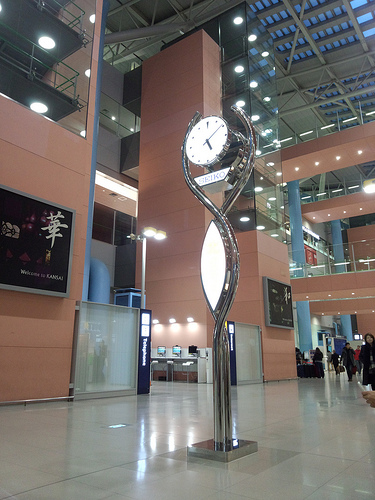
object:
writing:
[39, 203, 68, 256]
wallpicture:
[0, 183, 76, 300]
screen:
[261, 268, 300, 334]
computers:
[158, 343, 169, 358]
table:
[154, 356, 197, 366]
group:
[296, 332, 374, 377]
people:
[309, 343, 327, 380]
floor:
[5, 402, 375, 498]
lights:
[230, 9, 247, 34]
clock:
[180, 116, 232, 167]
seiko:
[195, 169, 225, 181]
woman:
[358, 332, 372, 395]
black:
[355, 343, 374, 387]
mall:
[1, 2, 367, 485]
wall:
[2, 97, 80, 402]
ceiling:
[117, 5, 374, 113]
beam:
[291, 188, 322, 362]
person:
[350, 342, 363, 374]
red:
[354, 343, 361, 369]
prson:
[312, 345, 325, 379]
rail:
[9, 72, 93, 129]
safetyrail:
[6, 35, 85, 108]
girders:
[271, 49, 374, 82]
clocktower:
[180, 107, 262, 461]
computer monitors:
[169, 345, 184, 355]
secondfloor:
[2, 48, 95, 127]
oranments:
[180, 102, 256, 216]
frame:
[200, 195, 249, 453]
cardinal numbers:
[186, 141, 195, 153]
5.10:
[184, 117, 230, 165]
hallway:
[154, 342, 336, 425]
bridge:
[282, 120, 374, 182]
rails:
[277, 118, 364, 149]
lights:
[310, 157, 322, 167]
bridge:
[300, 187, 374, 227]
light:
[199, 222, 231, 304]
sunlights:
[264, 7, 363, 108]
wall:
[147, 232, 204, 328]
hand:
[362, 391, 373, 403]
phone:
[349, 371, 370, 394]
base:
[187, 435, 267, 464]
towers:
[130, 314, 154, 388]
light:
[140, 315, 154, 336]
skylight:
[248, 1, 363, 123]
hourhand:
[205, 137, 213, 150]